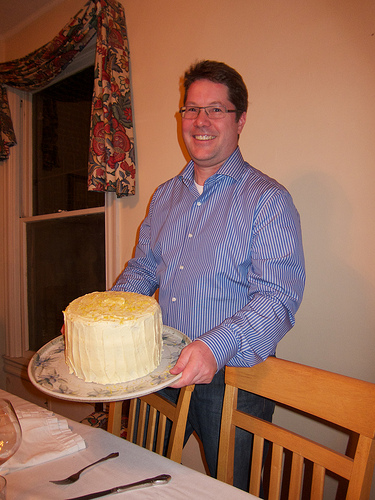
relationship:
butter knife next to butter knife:
[70, 473, 172, 499] [70, 472, 173, 498]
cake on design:
[63, 290, 165, 385] [26, 324, 193, 403]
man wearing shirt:
[107, 63, 309, 491] [111, 146, 307, 371]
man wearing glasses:
[107, 63, 309, 491] [178, 102, 239, 121]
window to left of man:
[25, 60, 104, 355] [107, 63, 309, 491]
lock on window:
[57, 207, 69, 214] [25, 60, 104, 355]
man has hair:
[107, 63, 309, 491] [182, 60, 248, 121]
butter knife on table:
[70, 473, 172, 499] [0, 389, 262, 500]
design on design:
[35, 327, 190, 400] [26, 324, 193, 403]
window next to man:
[25, 60, 104, 355] [107, 63, 309, 491]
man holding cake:
[107, 63, 309, 491] [63, 290, 165, 385]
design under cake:
[26, 324, 193, 403] [63, 290, 165, 385]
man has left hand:
[107, 63, 309, 491] [169, 338, 219, 387]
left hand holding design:
[169, 338, 219, 387] [26, 324, 193, 403]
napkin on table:
[0, 405, 86, 475] [1, 389, 262, 499]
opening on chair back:
[232, 426, 251, 489] [218, 355, 373, 499]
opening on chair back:
[236, 385, 360, 459] [218, 355, 373, 499]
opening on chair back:
[299, 458, 313, 499] [218, 355, 373, 499]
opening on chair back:
[323, 467, 355, 493] [218, 355, 373, 499]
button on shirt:
[196, 202, 201, 207] [111, 146, 307, 371]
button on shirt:
[187, 232, 195, 238] [111, 146, 307, 371]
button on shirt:
[178, 265, 186, 271] [111, 146, 307, 371]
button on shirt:
[171, 298, 179, 303] [111, 146, 307, 371]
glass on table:
[2, 400, 25, 491] [1, 389, 262, 499]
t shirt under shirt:
[193, 179, 206, 193] [111, 146, 307, 371]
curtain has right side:
[0, 0, 137, 196] [88, 2, 139, 198]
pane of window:
[31, 66, 106, 214] [25, 60, 104, 355]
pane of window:
[24, 213, 107, 350] [25, 60, 104, 355]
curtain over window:
[0, 0, 137, 196] [25, 60, 104, 355]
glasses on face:
[178, 102, 239, 121] [181, 80, 236, 165]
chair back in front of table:
[218, 355, 373, 499] [1, 389, 262, 499]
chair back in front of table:
[109, 382, 194, 466] [1, 389, 262, 499]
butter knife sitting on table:
[70, 473, 172, 499] [1, 389, 262, 499]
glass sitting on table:
[2, 400, 25, 491] [1, 389, 262, 499]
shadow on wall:
[273, 168, 374, 382] [4, 0, 373, 478]